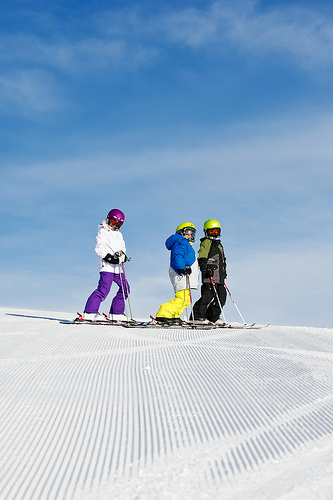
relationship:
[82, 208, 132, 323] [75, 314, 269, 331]
girl on skis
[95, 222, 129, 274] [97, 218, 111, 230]
jacket has a hood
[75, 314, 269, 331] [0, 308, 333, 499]
skis are in snow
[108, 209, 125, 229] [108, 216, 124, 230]
helmet has a visor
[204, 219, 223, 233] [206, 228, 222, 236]
helmet has a visor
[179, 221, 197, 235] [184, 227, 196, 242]
helmet has a visor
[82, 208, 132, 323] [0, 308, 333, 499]
girl in snow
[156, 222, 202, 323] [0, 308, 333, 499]
woman in snow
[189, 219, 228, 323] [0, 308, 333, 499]
man in snow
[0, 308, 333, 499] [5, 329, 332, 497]
snow has a pattern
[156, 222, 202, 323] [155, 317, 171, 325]
woman wearing boot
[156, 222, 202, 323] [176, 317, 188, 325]
woman wearing boot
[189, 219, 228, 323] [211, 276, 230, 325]
man holding rod